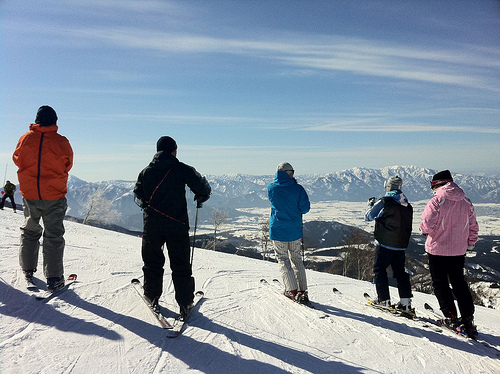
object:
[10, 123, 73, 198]
jacket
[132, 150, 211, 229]
jacket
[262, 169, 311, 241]
jacket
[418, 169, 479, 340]
person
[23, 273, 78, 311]
skis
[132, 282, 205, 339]
skis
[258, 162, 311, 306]
person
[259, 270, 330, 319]
skis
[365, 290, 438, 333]
skis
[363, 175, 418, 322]
skier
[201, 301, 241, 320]
skitracks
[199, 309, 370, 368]
snow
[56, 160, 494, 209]
mountain range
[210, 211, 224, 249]
tree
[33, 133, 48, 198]
stripe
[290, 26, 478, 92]
clouds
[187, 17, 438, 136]
sky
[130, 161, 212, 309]
ski outfit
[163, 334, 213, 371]
shadows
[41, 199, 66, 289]
leg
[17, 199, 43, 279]
leg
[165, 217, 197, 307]
leg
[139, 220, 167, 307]
leg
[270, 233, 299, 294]
leg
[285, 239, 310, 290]
leg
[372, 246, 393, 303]
leg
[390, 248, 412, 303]
leg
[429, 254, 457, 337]
leg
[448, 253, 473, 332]
leg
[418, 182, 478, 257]
coat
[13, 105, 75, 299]
man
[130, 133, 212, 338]
man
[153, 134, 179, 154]
hat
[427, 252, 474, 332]
pants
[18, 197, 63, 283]
pants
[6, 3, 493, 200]
background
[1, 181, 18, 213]
man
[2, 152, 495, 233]
distance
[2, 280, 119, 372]
shadows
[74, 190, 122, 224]
trees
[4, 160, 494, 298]
background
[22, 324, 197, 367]
ground